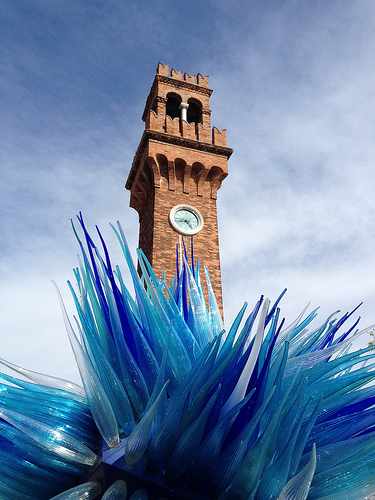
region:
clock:
[168, 190, 207, 245]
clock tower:
[139, 46, 223, 263]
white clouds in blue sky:
[285, 45, 322, 78]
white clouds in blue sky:
[259, 166, 286, 184]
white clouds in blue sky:
[280, 224, 302, 254]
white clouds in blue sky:
[252, 96, 299, 143]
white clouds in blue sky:
[176, 16, 221, 59]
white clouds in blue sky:
[15, 9, 61, 49]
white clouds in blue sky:
[49, 117, 99, 170]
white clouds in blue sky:
[46, 158, 106, 191]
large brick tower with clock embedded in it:
[119, 56, 243, 334]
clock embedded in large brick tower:
[166, 197, 206, 240]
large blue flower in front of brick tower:
[1, 210, 373, 495]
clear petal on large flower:
[42, 272, 126, 447]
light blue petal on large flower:
[60, 277, 132, 430]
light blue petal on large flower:
[0, 380, 93, 418]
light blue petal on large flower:
[0, 367, 87, 406]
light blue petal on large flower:
[163, 275, 200, 359]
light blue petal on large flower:
[135, 245, 195, 375]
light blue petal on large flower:
[114, 217, 178, 391]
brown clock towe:
[135, 51, 223, 253]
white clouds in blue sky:
[301, 251, 324, 286]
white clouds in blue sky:
[307, 197, 329, 225]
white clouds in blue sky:
[41, 152, 79, 175]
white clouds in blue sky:
[291, 132, 325, 196]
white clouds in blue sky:
[275, 72, 298, 99]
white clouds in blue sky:
[42, 128, 70, 147]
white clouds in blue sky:
[19, 20, 65, 99]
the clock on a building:
[156, 185, 219, 257]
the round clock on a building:
[161, 192, 218, 242]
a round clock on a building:
[163, 196, 218, 245]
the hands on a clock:
[158, 189, 221, 251]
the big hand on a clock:
[162, 185, 214, 258]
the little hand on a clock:
[165, 179, 230, 251]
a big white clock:
[167, 177, 218, 245]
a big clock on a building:
[141, 166, 235, 254]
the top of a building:
[152, 57, 227, 115]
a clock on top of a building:
[117, 84, 254, 301]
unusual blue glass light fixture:
[1, 211, 373, 499]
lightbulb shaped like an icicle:
[50, 278, 121, 448]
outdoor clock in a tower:
[166, 202, 201, 234]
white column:
[174, 98, 183, 116]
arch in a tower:
[160, 86, 179, 101]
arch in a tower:
[182, 92, 201, 110]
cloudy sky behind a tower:
[0, 0, 371, 383]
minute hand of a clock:
[170, 213, 186, 221]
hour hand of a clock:
[183, 217, 192, 228]